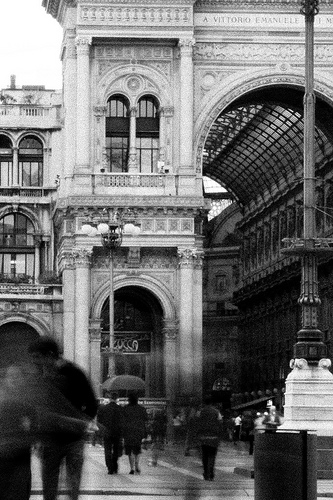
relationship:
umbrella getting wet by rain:
[187, 388, 232, 418] [42, 192, 284, 433]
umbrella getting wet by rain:
[102, 372, 146, 391] [55, 212, 260, 448]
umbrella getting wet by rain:
[79, 213, 144, 246] [35, 148, 260, 421]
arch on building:
[100, 285, 165, 402] [34, 89, 252, 440]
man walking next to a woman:
[98, 394, 122, 473] [126, 395, 144, 468]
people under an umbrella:
[96, 393, 148, 475] [101, 369, 153, 395]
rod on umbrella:
[119, 391, 125, 409] [104, 371, 151, 393]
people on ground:
[23, 338, 262, 488] [31, 441, 253, 500]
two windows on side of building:
[98, 82, 164, 172] [9, 116, 306, 424]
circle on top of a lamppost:
[81, 223, 140, 237] [103, 248, 119, 378]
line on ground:
[145, 449, 207, 484] [39, 440, 255, 490]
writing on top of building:
[196, 14, 320, 28] [16, 8, 284, 426]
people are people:
[96, 393, 148, 475] [96, 393, 148, 475]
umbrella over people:
[102, 372, 146, 391] [96, 398, 146, 477]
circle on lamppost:
[81, 223, 140, 237] [103, 248, 119, 378]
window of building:
[15, 253, 33, 278] [4, 1, 283, 444]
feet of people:
[106, 467, 142, 474] [96, 392, 149, 474]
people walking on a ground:
[96, 393, 148, 475] [31, 441, 253, 500]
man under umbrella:
[97, 393, 123, 475] [101, 369, 153, 395]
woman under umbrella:
[124, 392, 144, 472] [101, 369, 153, 395]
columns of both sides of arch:
[63, 242, 204, 413] [100, 285, 165, 402]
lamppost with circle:
[101, 242, 119, 404] [81, 223, 140, 237]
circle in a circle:
[81, 223, 140, 237] [81, 219, 143, 238]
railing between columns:
[97, 174, 163, 189] [76, 39, 192, 193]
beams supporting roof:
[195, 59, 320, 204] [200, 32, 316, 80]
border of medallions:
[226, 263, 289, 281] [240, 191, 319, 264]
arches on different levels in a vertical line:
[2, 125, 50, 288] [15, 121, 35, 277]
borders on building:
[199, 13, 306, 58] [62, 4, 318, 315]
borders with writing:
[199, 13, 306, 58] [201, 13, 322, 24]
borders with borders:
[199, 13, 306, 58] [193, 44, 333, 59]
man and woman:
[98, 394, 122, 473] [122, 392, 147, 473]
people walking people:
[99, 392, 151, 471] [96, 393, 148, 475]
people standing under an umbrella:
[96, 393, 148, 475] [101, 369, 152, 392]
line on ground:
[148, 459, 205, 481] [13, 425, 293, 490]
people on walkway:
[0, 335, 257, 500] [51, 434, 255, 481]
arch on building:
[93, 280, 171, 390] [59, 10, 202, 419]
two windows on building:
[105, 92, 160, 173] [56, 12, 257, 449]